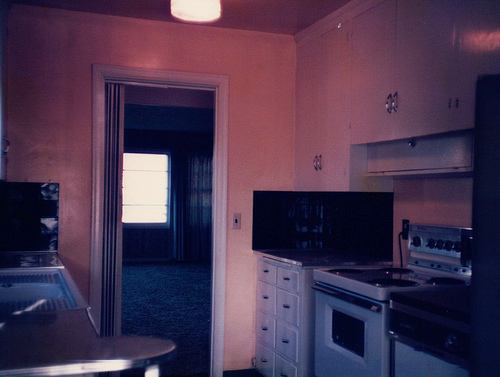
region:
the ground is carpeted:
[154, 268, 201, 330]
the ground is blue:
[148, 266, 196, 319]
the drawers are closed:
[252, 266, 308, 368]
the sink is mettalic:
[29, 259, 56, 309]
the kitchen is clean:
[10, 106, 378, 372]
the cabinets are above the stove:
[303, 116, 460, 139]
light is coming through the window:
[125, 152, 176, 227]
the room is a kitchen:
[10, 105, 471, 371]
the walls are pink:
[246, 118, 301, 180]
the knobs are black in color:
[407, 236, 469, 265]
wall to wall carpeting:
[118, 237, 213, 375]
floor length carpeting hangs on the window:
[145, 135, 190, 261]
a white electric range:
[308, 185, 471, 375]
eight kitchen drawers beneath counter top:
[249, 246, 311, 375]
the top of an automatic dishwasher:
[378, 288, 480, 375]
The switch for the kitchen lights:
[230, 200, 246, 255]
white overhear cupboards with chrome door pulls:
[290, 1, 465, 209]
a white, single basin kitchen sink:
[1, 254, 99, 325]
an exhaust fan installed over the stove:
[341, 128, 484, 258]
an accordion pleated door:
[94, 58, 153, 355]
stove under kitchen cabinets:
[295, 204, 479, 368]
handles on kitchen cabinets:
[377, 87, 407, 120]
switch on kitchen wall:
[223, 208, 247, 242]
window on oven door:
[315, 303, 371, 363]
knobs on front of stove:
[408, 228, 458, 251]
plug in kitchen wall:
[390, 214, 415, 250]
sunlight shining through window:
[110, 141, 177, 236]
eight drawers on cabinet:
[246, 257, 301, 375]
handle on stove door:
[312, 279, 380, 313]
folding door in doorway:
[91, 79, 128, 318]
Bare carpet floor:
[105, 251, 222, 372]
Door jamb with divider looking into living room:
[87, 50, 247, 375]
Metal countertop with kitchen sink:
[0, 239, 184, 371]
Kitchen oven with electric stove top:
[308, 196, 481, 375]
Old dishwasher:
[365, 288, 480, 372]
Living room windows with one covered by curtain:
[115, 80, 220, 365]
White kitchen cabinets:
[286, 6, 493, 201]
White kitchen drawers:
[242, 245, 319, 375]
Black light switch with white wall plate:
[218, 201, 265, 242]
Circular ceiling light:
[105, 2, 364, 71]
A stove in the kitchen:
[206, 130, 478, 372]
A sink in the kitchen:
[10, 249, 55, 326]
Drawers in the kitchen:
[257, 262, 284, 372]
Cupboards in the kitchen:
[299, 111, 348, 197]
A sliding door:
[98, 87, 301, 349]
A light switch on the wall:
[225, 207, 240, 222]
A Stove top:
[371, 254, 426, 366]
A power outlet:
[396, 208, 416, 253]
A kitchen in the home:
[46, 130, 356, 278]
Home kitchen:
[58, 101, 270, 293]